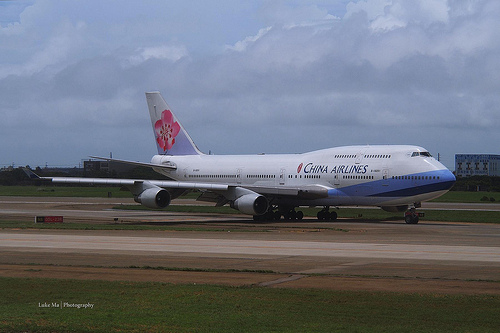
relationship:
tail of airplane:
[96, 87, 200, 182] [17, 85, 459, 235]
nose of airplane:
[435, 166, 456, 195] [20, 90, 457, 225]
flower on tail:
[153, 107, 180, 156] [139, 86, 209, 152]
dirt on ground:
[4, 249, 499, 292] [4, 187, 495, 332]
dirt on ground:
[153, 222, 498, 236] [4, 187, 495, 332]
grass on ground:
[5, 273, 498, 331] [0, 275, 498, 332]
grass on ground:
[428, 209, 498, 221] [0, 275, 498, 332]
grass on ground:
[4, 215, 267, 232] [0, 275, 498, 332]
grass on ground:
[0, 185, 121, 194] [0, 275, 498, 332]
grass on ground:
[0, 185, 499, 203] [0, 275, 498, 332]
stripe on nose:
[360, 166, 461, 190] [372, 150, 483, 237]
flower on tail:
[149, 107, 180, 154] [144, 88, 202, 155]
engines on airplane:
[130, 182, 270, 217] [20, 90, 457, 225]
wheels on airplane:
[246, 192, 430, 237] [20, 90, 457, 225]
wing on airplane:
[35, 175, 335, 217] [20, 90, 457, 225]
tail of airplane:
[140, 90, 204, 157] [87, 73, 474, 240]